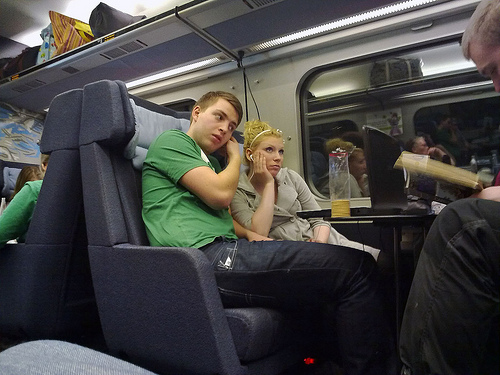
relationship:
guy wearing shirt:
[139, 88, 391, 374] [137, 127, 239, 249]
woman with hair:
[229, 114, 387, 269] [240, 117, 288, 150]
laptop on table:
[292, 122, 408, 218] [320, 213, 441, 355]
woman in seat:
[229, 114, 387, 269] [81, 76, 301, 373]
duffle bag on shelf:
[367, 53, 424, 87] [309, 60, 490, 109]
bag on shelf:
[86, 2, 150, 38] [0, 0, 265, 121]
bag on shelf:
[46, 11, 94, 55] [0, 0, 265, 121]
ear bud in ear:
[249, 154, 253, 162] [241, 147, 255, 167]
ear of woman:
[241, 147, 255, 167] [229, 114, 387, 269]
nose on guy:
[218, 118, 231, 138] [139, 88, 391, 374]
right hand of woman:
[249, 149, 275, 188] [229, 114, 387, 269]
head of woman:
[240, 117, 286, 180] [229, 114, 387, 269]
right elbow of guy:
[201, 182, 241, 215] [139, 88, 391, 374]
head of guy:
[186, 88, 246, 150] [139, 88, 391, 374]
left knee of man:
[422, 197, 499, 263] [389, 1, 499, 374]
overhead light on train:
[115, 0, 435, 90] [1, 0, 499, 374]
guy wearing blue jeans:
[139, 88, 391, 374] [196, 233, 386, 374]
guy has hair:
[139, 88, 391, 374] [193, 90, 245, 120]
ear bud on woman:
[249, 154, 253, 162] [229, 114, 387, 269]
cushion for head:
[126, 100, 195, 168] [186, 88, 246, 150]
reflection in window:
[315, 133, 499, 188] [299, 80, 499, 219]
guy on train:
[139, 88, 391, 374] [1, 0, 499, 374]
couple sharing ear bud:
[133, 83, 386, 306] [249, 154, 253, 162]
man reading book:
[389, 1, 499, 374] [388, 145, 491, 206]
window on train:
[299, 80, 499, 219] [1, 0, 499, 374]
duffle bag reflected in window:
[367, 53, 424, 87] [299, 80, 499, 219]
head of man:
[456, 1, 499, 95] [389, 1, 499, 374]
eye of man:
[485, 64, 499, 82] [389, 1, 499, 374]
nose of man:
[487, 81, 499, 94] [389, 1, 499, 374]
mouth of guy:
[208, 132, 222, 146] [139, 88, 391, 374]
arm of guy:
[154, 131, 243, 210] [139, 88, 391, 374]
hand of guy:
[223, 134, 241, 160] [139, 88, 391, 374]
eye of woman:
[276, 147, 285, 157] [229, 114, 387, 269]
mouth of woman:
[269, 163, 285, 172] [229, 114, 387, 269]